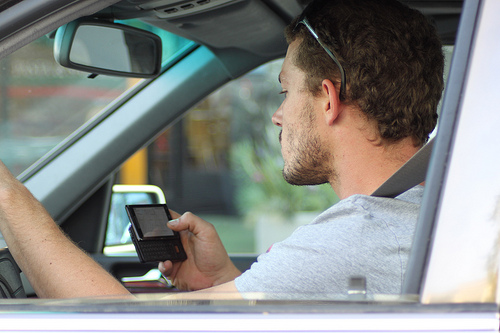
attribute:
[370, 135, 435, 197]
seat belt — grey 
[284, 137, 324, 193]
beard — fuzzy 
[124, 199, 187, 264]
phone — black 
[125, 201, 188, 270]
phone — black 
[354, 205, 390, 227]
spot — small, round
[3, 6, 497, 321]
window — open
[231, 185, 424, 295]
shirt — gray